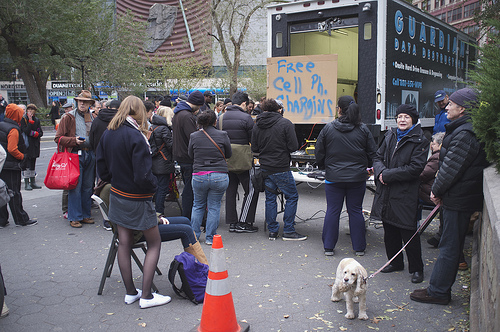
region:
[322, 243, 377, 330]
white dog on a leash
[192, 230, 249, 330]
yellow parking cone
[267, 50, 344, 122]
free cell phone chargers sign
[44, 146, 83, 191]
red shopping bag on man's arm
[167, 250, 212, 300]
purple bag laying on the ground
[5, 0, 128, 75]
tree in the distance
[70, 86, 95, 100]
brown hat on man's head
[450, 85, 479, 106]
blue ski hat on man's head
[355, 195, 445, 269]
pink leash on mans hand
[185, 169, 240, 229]
blue jeans on girl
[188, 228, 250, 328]
orange and white safety cone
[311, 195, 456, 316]
small white dog on a leash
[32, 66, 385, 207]
people standing at cell phone charging station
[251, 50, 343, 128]
cardboard sign offering free cell phone chargingg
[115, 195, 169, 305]
woman wearing black nylons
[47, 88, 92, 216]
man with red shopping bag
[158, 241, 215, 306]
purple backpack on the ground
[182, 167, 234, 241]
woman wearing blue jeans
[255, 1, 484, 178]
large black truck with blue lettering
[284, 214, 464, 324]
leaves scattered on the ground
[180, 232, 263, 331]
Orange traffic cone with gray strips near top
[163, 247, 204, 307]
Purple backpack with black straps on the ground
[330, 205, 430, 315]
Small beige dog on a leash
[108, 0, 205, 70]
Large gray tarp hanging from a brown structure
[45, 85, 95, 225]
Elderly man carrying a red shopping bag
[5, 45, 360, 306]
Group of people waiting to charge their cell phones for free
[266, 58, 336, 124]
Cardboard sign with blue writing offering free charging of cell phones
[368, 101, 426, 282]
Woman wearing a black hat and a blue scarf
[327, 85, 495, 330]
Man with a dog on a leash leaning against a stone wall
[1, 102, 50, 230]
Person wearing a black vest over an orange hoodie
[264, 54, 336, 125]
A large cardboard sign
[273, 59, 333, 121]
Blue writing on the sign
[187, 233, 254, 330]
An orange and white traffic cone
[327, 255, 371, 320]
A small white dog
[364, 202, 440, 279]
A long dog's leash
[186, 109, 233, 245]
A woman in a black jacket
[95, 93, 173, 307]
A woman wearing a skirt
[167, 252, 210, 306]
A purple backpack on the ground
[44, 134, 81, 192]
A large red bag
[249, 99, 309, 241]
A man in a black hoodie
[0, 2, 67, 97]
tree at background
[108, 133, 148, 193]
woman wearing blue jacket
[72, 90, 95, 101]
man wearing brown hat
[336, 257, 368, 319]
white color dog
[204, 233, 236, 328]
orange cone with kept on ground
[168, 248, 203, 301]
black and violet color bag pack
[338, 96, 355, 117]
woman with pony tail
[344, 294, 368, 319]
front legs of the dog